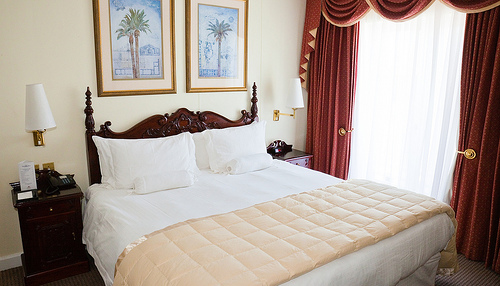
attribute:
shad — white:
[17, 73, 55, 142]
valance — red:
[297, 5, 498, 81]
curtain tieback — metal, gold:
[448, 144, 477, 165]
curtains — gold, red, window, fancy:
[290, 4, 497, 260]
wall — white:
[4, 9, 307, 276]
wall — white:
[6, 0, 304, 254]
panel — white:
[347, 10, 469, 209]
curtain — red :
[305, 25, 376, 170]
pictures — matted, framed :
[85, 3, 254, 94]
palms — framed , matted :
[91, 6, 245, 101]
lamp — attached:
[12, 77, 64, 167]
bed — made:
[58, 106, 364, 276]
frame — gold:
[92, 0, 174, 95]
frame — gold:
[182, 1, 252, 94]